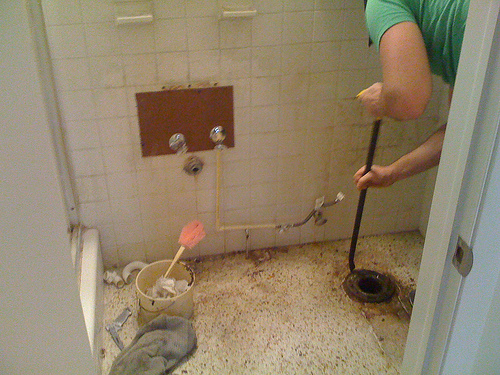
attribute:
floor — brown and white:
[255, 246, 347, 341]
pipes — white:
[101, 257, 150, 289]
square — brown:
[133, 85, 235, 156]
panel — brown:
[128, 78, 246, 153]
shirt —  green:
[365, 0, 462, 79]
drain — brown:
[338, 264, 406, 308]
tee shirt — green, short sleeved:
[361, 2, 466, 83]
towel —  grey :
[121, 313, 209, 372]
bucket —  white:
[131, 250, 259, 348]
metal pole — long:
[336, 116, 383, 286]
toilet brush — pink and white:
[163, 206, 228, 263]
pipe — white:
[208, 128, 345, 237]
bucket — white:
[130, 255, 197, 325]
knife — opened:
[105, 305, 132, 351]